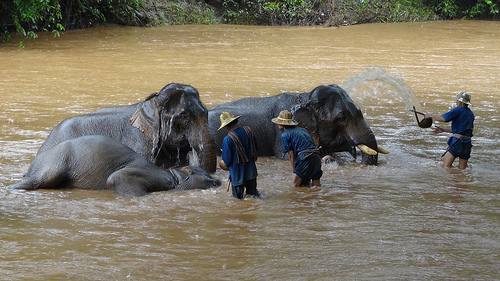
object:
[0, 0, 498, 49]
trees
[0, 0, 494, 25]
shrubs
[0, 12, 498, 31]
bank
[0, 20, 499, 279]
ripples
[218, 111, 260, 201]
men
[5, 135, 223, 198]
elephant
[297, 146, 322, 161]
sash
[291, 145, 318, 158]
waist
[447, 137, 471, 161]
shorts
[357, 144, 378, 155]
tusk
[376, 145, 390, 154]
tusk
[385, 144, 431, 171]
waves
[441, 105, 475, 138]
shirt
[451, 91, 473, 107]
straw hats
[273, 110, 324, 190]
men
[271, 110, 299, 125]
hat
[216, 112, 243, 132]
hat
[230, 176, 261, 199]
pants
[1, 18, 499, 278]
river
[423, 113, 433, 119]
hand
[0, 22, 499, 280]
water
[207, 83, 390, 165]
elephant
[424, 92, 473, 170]
man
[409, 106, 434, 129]
water holder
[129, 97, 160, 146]
ear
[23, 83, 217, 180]
elephant